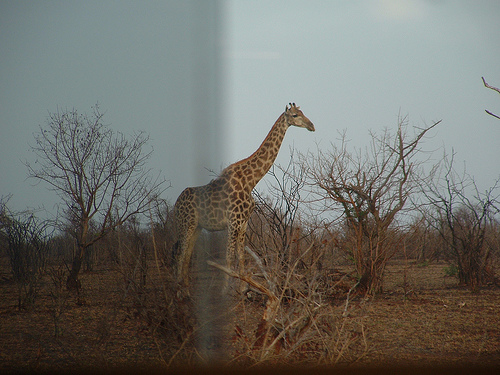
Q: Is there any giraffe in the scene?
A: Yes, there is a giraffe.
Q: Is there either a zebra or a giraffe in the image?
A: Yes, there is a giraffe.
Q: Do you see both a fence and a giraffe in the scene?
A: No, there is a giraffe but no fences.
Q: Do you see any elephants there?
A: No, there are no elephants.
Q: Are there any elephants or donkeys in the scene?
A: No, there are no elephants or donkeys.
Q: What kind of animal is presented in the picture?
A: The animal is a giraffe.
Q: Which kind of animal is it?
A: The animal is a giraffe.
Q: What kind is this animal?
A: This is a giraffe.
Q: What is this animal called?
A: This is a giraffe.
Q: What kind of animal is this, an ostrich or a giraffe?
A: This is a giraffe.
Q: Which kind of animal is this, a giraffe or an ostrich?
A: This is a giraffe.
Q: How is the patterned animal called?
A: The animal is a giraffe.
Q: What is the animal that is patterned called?
A: The animal is a giraffe.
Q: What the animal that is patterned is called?
A: The animal is a giraffe.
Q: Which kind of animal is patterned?
A: The animal is a giraffe.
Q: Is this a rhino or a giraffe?
A: This is a giraffe.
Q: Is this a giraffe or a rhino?
A: This is a giraffe.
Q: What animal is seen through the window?
A: The giraffe is seen through the window.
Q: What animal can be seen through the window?
A: The giraffe is seen through the window.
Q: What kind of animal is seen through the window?
A: The animal is a giraffe.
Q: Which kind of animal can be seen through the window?
A: The animal is a giraffe.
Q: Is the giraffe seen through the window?
A: Yes, the giraffe is seen through the window.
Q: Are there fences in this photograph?
A: No, there are no fences.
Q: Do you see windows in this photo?
A: Yes, there is a window.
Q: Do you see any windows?
A: Yes, there is a window.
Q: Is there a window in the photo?
A: Yes, there is a window.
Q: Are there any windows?
A: Yes, there is a window.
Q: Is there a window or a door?
A: Yes, there is a window.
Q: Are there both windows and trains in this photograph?
A: No, there is a window but no trains.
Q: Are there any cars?
A: No, there are no cars.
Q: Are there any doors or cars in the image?
A: No, there are no cars or doors.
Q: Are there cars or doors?
A: No, there are no cars or doors.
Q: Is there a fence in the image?
A: No, there are no fences.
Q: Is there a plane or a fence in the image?
A: No, there are no fences or airplanes.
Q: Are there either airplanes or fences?
A: No, there are no fences or airplanes.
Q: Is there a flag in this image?
A: No, there are no flags.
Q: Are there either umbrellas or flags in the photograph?
A: No, there are no flags or umbrellas.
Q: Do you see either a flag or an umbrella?
A: No, there are no flags or umbrellas.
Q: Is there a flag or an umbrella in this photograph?
A: No, there are no flags or umbrellas.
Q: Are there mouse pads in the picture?
A: No, there are no mouse pads.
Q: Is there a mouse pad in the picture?
A: No, there are no mouse pads.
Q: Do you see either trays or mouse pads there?
A: No, there are no mouse pads or trays.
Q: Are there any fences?
A: No, there are no fences.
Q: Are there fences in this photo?
A: No, there are no fences.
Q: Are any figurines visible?
A: No, there are no figurines.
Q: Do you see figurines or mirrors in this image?
A: No, there are no figurines or mirrors.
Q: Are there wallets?
A: No, there are no wallets.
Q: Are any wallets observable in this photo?
A: No, there are no wallets.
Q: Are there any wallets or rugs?
A: No, there are no wallets or rugs.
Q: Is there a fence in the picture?
A: No, there are no fences.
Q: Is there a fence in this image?
A: No, there are no fences.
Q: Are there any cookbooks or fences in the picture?
A: No, there are no fences or cookbooks.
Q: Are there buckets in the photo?
A: No, there are no buckets.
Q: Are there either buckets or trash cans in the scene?
A: No, there are no buckets or trash cans.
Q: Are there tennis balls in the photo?
A: No, there are no tennis balls.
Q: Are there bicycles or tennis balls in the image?
A: No, there are no tennis balls or bicycles.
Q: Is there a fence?
A: No, there are no fences.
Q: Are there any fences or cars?
A: No, there are no fences or cars.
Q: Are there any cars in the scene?
A: No, there are no cars.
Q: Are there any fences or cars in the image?
A: No, there are no cars or fences.